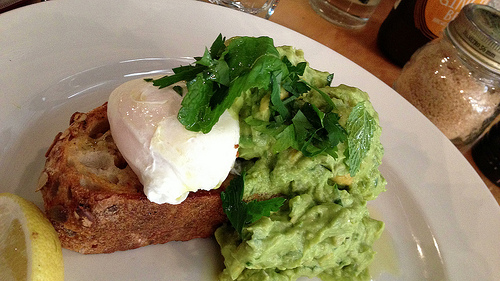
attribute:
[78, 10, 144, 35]
plate — white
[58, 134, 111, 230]
bread — here, sliced, brown, toasted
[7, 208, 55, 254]
lemon — wedge, rhine, fleshy, wdge, yellow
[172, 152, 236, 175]
sour cream — some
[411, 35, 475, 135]
jar — glass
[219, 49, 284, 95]
leaves — mint, garnished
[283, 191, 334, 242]
guacamole — green, here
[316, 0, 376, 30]
glass — small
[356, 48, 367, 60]
table — brown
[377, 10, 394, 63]
bottle — small, clear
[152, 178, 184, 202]
butter — scoop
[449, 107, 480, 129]
spices — here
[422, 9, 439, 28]
sticker — orange